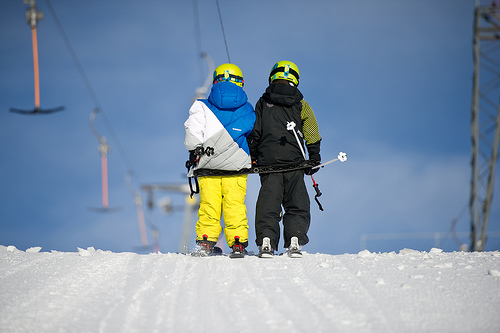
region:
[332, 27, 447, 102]
this is the sky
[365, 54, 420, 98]
the sky is blue in color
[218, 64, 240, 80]
this is a helmet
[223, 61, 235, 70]
the helmet is yellow in color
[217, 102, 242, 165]
this is a jacket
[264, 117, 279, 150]
the jacket is black in color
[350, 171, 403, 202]
these are the clouds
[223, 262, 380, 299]
this is a snow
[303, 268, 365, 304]
the snow is white in color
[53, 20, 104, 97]
this is a wire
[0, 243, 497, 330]
Ground covered by snow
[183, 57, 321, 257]
Two people at the top of a ski slope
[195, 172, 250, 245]
A pair of yellow snowpants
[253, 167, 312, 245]
A pair of black snowpants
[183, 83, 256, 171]
A blue and white jacket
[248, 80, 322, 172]
A black jacket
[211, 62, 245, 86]
A yellow helmet worn by a person wearing yellow pants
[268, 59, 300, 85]
A yellow helmet worn by a person wearing black pants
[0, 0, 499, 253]
Blue sky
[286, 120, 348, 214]
A pair of white ski poles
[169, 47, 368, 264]
two skiers standing on snow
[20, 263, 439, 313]
white snow on the ground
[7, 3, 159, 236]
ski lift to the left of skiers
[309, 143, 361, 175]
ski pole used for balance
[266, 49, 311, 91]
yellow helmet of a skier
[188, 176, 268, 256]
yellow ski pants of a skier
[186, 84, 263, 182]
blue and white ski jacket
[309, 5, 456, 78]
blue sky in the distance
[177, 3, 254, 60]
wires in the air for the ski lift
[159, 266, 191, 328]
ski track in the snow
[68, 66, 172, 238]
A sky lift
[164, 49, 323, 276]
Two people standing at the top of a slope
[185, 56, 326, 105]
Two yellow safety helmets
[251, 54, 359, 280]
A person holding poles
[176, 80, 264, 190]
Wearing a blue and white coat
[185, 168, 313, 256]
Yellow and black pants contrasting each other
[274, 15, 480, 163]
A beautiful blue sky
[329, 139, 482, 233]
Light white clouds in the sky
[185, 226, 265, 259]
Black ski boots with red trim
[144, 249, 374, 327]
Tracks in the snow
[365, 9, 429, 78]
part of the sky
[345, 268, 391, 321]
part of a snow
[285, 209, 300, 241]
part of a track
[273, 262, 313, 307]
part of some lines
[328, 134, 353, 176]
part of a hooker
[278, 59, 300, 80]
part of a helmet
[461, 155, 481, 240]
part of a post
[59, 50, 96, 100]
part of a wire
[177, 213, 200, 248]
part of a post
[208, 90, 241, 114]
part of a hood